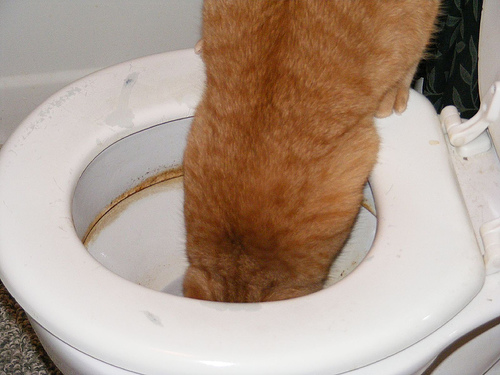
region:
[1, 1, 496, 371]
cat with head in toilet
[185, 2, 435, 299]
striped orange cat fur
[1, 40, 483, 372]
seat on top of toilet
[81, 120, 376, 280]
rust stain in toilet bowl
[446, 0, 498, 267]
underside of toilet lit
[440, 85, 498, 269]
mechanism on back of toilet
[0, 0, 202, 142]
side of white tub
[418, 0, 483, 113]
leaves on shower curtain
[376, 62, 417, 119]
cat foot on toilet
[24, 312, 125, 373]
outside of toilet bowl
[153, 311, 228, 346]
White seat on toilet.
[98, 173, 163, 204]
Brown ring on inside of toilet.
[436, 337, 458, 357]
White toilet in room.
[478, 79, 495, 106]
White lid on toilet.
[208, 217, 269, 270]
Stripes in cat's fur.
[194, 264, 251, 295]
Cat's head is inside of toilet.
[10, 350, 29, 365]
Gray rug on ground.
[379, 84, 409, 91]
Cat has orange paw.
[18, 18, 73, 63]
White wall in room.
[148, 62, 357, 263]
Cat is bending down into toilet.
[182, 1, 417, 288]
tabby reaching in toilet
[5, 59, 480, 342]
white toilet seat on bowl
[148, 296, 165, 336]
black scoff on toilet seat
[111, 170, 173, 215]
rusty ring around toilet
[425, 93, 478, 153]
hinge on back of seat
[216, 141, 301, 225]
tan fur of cat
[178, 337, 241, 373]
light reflecting off toilet seat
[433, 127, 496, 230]
dirt on back of toilet seat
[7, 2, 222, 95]
white wall next to toilet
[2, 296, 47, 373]
gray carpet under toilet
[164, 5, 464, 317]
orange kitty drinking out of a toilet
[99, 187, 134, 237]
dirt along side of the toilet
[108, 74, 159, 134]
peeling toilet seat on the toilet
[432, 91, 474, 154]
hinge that holds the toilet lid together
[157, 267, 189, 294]
water in the white toilet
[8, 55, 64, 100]
white molding along the wall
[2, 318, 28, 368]
blue berber carpeting on the floor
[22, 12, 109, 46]
white paint on the wall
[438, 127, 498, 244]
dirt on the back of the toilet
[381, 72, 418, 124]
kitty's back paw on the toilet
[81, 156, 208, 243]
brown line around the toilet bowl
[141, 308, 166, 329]
mark on the toilet seat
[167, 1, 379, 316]
cat with its head in the toilet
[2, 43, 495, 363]
toilet seat is down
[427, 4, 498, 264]
toilet lid is up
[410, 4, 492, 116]
green leaves on a black background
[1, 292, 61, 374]
carpet on the ground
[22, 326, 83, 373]
edge of the toilet bowl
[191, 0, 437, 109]
butt is sticking in the air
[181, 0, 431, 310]
brown fur on the cat